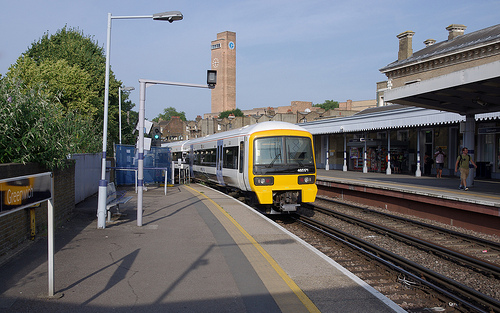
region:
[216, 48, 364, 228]
the front of a train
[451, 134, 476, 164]
the head of a man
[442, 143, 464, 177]
the arm of a man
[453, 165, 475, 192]
the legs of a man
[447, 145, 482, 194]
a man wearing shorts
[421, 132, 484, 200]
a main near a train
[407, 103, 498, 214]
a man at a train station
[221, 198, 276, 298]
a yellow line near a train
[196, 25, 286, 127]
a building in the background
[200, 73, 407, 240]
a train at a train station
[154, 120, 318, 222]
Train moving forward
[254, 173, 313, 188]
Headlights of the train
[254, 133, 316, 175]
Front window of the train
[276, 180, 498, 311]
Set of train tracks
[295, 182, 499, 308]
Gravel between the train tracks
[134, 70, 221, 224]
Night light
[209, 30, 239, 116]
Large brown building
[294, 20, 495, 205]
Train station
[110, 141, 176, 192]
Group of portable bathrooms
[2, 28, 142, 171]
Large tree on the side of the road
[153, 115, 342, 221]
Yellow and white train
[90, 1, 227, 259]
White street lamp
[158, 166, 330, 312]
Yellow line on sidewalk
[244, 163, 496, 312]
Brown train tracks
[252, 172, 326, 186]
Two black and silver lights on front of train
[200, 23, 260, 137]
Tall brown clock tower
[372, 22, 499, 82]
Black roof on grey building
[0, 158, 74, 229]
Black and yellow sign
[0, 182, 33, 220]
white lettering on sign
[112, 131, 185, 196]
Blue fence on sidewalk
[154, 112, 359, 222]
the front of the train is yellow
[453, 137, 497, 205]
he is walking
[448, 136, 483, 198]
he is wearing a grey tee shirt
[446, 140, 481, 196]
he is wearing his backpack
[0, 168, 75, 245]
the sign is black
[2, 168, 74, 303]
the sign post is white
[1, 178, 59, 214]
the sign says "Greenwich"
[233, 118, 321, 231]
the front of the train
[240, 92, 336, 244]
the front of the train is yellow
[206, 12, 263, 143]
there is a clock on this tower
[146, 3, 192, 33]
A light on top of a pole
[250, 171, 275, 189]
The right headlight of a train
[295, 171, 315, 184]
The left headlight of a train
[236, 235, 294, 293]
A yellow line painted on concrete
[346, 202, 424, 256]
Train tracks on wood and gravel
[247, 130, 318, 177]
The front windshield of a yellow train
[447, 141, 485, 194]
A person walking on a train platform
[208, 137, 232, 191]
The side doors of a train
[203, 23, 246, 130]
A tall buidling behind a train station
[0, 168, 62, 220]
A sign at a train station